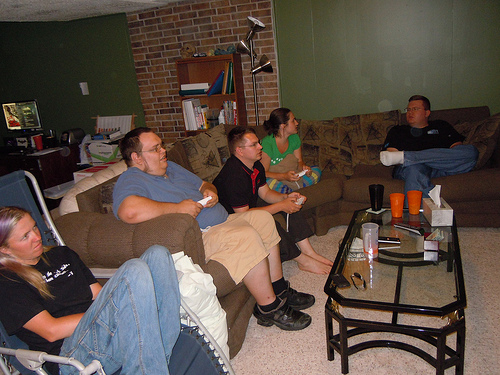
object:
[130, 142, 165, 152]
eyeglasses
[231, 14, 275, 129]
lamp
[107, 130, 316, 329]
man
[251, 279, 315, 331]
shoes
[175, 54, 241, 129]
books/shelf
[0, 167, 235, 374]
chair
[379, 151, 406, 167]
sock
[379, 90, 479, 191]
man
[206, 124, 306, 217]
man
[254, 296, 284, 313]
sock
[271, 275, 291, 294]
sock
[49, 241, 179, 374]
jeans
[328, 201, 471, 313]
surface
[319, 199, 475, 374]
table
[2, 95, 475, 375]
people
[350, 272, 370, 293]
sunglasses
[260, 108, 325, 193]
girl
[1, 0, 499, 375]
living room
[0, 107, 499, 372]
couch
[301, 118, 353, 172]
pillow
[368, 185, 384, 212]
black cup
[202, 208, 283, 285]
shorts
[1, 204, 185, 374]
woman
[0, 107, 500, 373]
fabric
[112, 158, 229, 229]
shirt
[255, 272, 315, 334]
feet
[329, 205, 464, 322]
glass